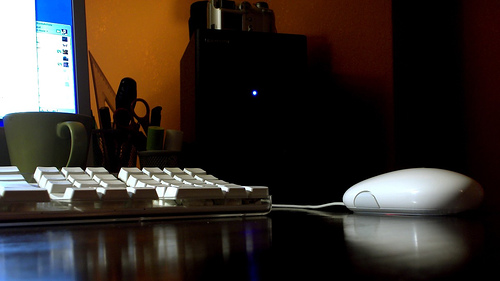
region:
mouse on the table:
[337, 156, 473, 234]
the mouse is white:
[336, 165, 486, 236]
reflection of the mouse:
[336, 171, 459, 266]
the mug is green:
[13, 101, 94, 177]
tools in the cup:
[102, 72, 148, 162]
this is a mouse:
[258, 130, 488, 240]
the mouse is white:
[252, 139, 499, 233]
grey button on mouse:
[345, 177, 380, 212]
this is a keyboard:
[0, 132, 282, 248]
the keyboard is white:
[5, 136, 270, 226]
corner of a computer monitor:
[5, 8, 99, 145]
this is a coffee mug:
[3, 91, 97, 191]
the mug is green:
[5, 86, 116, 201]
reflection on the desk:
[5, 209, 479, 274]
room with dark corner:
[0, 1, 498, 279]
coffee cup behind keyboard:
[0, 112, 272, 218]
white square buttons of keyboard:
[1, 164, 271, 221]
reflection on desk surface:
[1, 211, 497, 279]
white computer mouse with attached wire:
[272, 167, 482, 212]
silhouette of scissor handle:
[132, 97, 151, 132]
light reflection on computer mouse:
[343, 166, 482, 212]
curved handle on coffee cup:
[6, 111, 86, 181]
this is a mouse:
[263, 146, 483, 233]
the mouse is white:
[265, 134, 496, 237]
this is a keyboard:
[5, 148, 286, 231]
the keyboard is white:
[5, 136, 292, 248]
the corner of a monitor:
[5, 3, 113, 144]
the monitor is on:
[13, 3, 125, 152]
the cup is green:
[0, 86, 100, 202]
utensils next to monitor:
[83, 60, 188, 182]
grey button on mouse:
[348, 183, 385, 213]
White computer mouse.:
[337, 160, 482, 214]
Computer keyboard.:
[0, 161, 273, 231]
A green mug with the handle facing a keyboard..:
[1, 110, 87, 181]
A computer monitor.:
[0, 1, 92, 126]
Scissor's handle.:
[131, 96, 151, 136]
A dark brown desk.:
[0, 182, 498, 277]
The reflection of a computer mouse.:
[337, 211, 462, 263]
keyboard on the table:
[0, 139, 276, 229]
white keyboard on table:
[17, 150, 239, 223]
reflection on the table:
[346, 215, 445, 259]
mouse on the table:
[333, 150, 475, 213]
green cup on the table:
[7, 101, 94, 176]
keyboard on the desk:
[0, 154, 274, 226]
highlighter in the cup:
[142, 123, 169, 152]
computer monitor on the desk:
[14, 2, 98, 122]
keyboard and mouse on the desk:
[8, 145, 498, 243]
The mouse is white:
[290, 125, 482, 245]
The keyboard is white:
[17, 148, 285, 232]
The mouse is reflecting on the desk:
[317, 160, 478, 262]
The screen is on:
[0, 0, 110, 147]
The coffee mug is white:
[1, 101, 95, 182]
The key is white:
[114, 160, 146, 179]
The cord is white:
[265, 190, 361, 212]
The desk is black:
[5, 215, 459, 280]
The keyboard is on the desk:
[3, 147, 289, 233]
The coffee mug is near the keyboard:
[2, 102, 293, 230]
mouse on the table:
[303, 123, 469, 255]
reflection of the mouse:
[346, 214, 440, 243]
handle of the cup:
[52, 98, 109, 168]